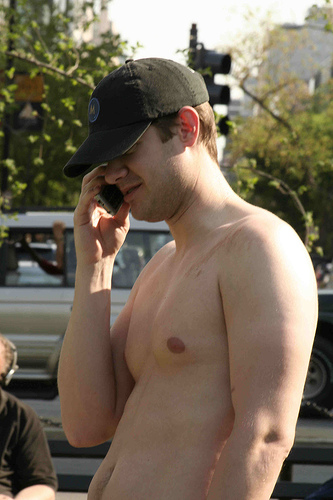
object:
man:
[56, 56, 322, 498]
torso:
[54, 210, 319, 499]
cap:
[62, 51, 211, 184]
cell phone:
[95, 182, 125, 217]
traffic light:
[185, 43, 235, 78]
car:
[0, 207, 178, 384]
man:
[0, 331, 60, 500]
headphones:
[4, 364, 19, 389]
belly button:
[104, 461, 117, 484]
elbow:
[245, 410, 297, 469]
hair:
[150, 100, 221, 170]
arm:
[52, 219, 67, 270]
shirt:
[0, 388, 60, 500]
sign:
[11, 73, 45, 136]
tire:
[299, 344, 333, 411]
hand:
[72, 161, 133, 265]